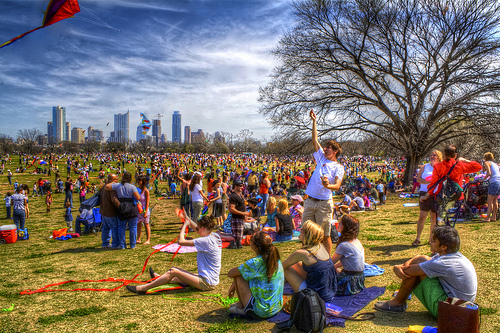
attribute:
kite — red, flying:
[1, 0, 86, 47]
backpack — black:
[288, 286, 328, 332]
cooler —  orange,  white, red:
[1, 221, 20, 247]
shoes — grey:
[372, 296, 410, 315]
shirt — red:
[427, 161, 481, 206]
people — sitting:
[280, 209, 388, 319]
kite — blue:
[138, 107, 153, 137]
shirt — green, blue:
[237, 256, 286, 318]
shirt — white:
[303, 147, 345, 200]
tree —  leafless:
[261, 1, 499, 146]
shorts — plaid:
[228, 216, 248, 242]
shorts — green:
[412, 270, 448, 316]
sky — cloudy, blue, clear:
[3, 4, 498, 135]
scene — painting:
[3, 3, 499, 332]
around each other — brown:
[96, 183, 121, 217]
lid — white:
[0, 221, 17, 232]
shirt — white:
[188, 182, 205, 202]